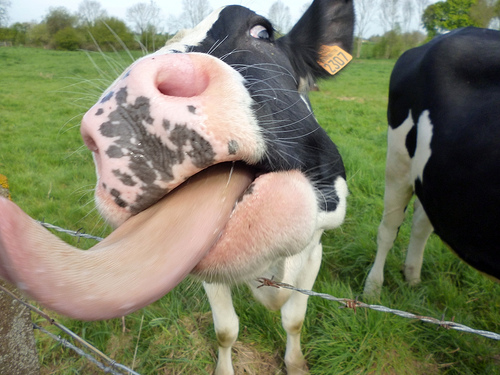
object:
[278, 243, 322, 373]
leg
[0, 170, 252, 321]
tongue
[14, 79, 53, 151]
grass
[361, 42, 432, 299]
back end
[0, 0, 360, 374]
cow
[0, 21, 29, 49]
tree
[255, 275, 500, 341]
barbed wire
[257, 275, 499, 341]
fence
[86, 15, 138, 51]
trees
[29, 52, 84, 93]
pasture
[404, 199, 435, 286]
leg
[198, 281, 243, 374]
leg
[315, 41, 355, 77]
orange tag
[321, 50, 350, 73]
2307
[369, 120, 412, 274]
back leg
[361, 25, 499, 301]
back`s cow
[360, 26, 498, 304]
half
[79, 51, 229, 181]
nose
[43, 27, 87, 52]
tree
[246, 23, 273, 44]
eye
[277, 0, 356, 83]
ear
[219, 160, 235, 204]
slobber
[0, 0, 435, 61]
bushes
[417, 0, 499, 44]
trees